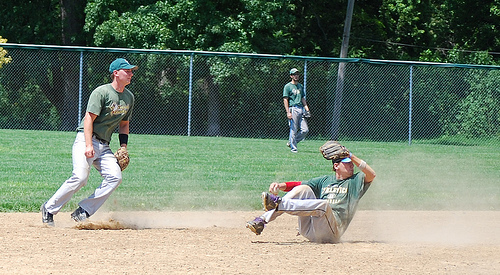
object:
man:
[42, 57, 139, 225]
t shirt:
[77, 85, 136, 139]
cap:
[108, 58, 135, 74]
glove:
[113, 147, 131, 170]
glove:
[318, 140, 349, 160]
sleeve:
[284, 181, 303, 193]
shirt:
[281, 82, 308, 108]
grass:
[175, 139, 202, 156]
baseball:
[4, 59, 497, 272]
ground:
[3, 243, 500, 274]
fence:
[424, 64, 500, 89]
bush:
[471, 53, 489, 63]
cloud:
[385, 185, 424, 208]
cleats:
[244, 217, 266, 235]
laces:
[254, 217, 264, 224]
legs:
[260, 191, 336, 231]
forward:
[130, 68, 142, 238]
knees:
[99, 170, 124, 184]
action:
[244, 141, 376, 243]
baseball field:
[2, 125, 498, 273]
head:
[332, 155, 354, 176]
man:
[282, 68, 312, 152]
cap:
[290, 68, 299, 74]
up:
[329, 6, 481, 27]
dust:
[78, 218, 142, 232]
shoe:
[71, 207, 92, 224]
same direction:
[425, 97, 477, 241]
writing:
[108, 102, 130, 115]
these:
[84, 2, 118, 23]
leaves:
[140, 21, 154, 27]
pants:
[43, 130, 124, 215]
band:
[119, 133, 128, 146]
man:
[246, 142, 378, 246]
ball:
[270, 186, 280, 195]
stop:
[30, 57, 138, 227]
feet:
[37, 202, 57, 229]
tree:
[55, 0, 84, 132]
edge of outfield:
[6, 128, 499, 150]